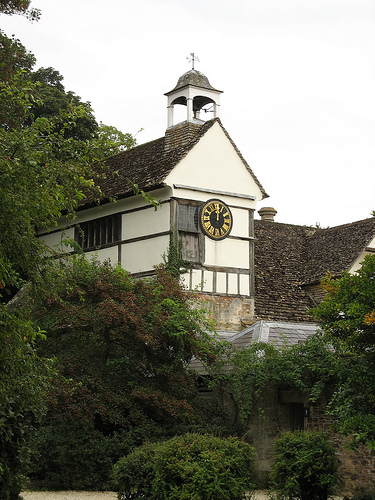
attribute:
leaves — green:
[80, 414, 123, 459]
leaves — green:
[170, 437, 247, 491]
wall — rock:
[309, 383, 374, 497]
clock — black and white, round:
[200, 198, 231, 238]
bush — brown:
[114, 431, 257, 498]